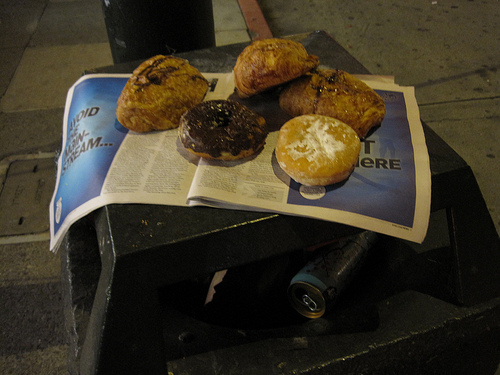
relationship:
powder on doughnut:
[291, 117, 347, 167] [272, 110, 363, 191]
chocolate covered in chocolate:
[180, 100, 268, 158] [180, 100, 268, 158]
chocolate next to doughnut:
[180, 100, 268, 158] [272, 110, 363, 191]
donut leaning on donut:
[229, 33, 321, 103] [272, 60, 388, 144]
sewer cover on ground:
[0, 158, 51, 237] [0, 2, 499, 374]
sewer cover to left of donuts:
[0, 158, 51, 237] [115, 37, 385, 187]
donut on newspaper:
[229, 33, 321, 103] [43, 68, 437, 258]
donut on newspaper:
[272, 60, 388, 144] [43, 68, 437, 258]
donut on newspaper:
[114, 49, 213, 136] [43, 68, 437, 258]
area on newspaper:
[104, 73, 289, 204] [43, 68, 437, 258]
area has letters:
[104, 73, 289, 204] [124, 143, 157, 155]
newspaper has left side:
[43, 68, 437, 258] [52, 77, 130, 235]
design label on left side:
[55, 197, 63, 224] [52, 77, 130, 235]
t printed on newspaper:
[360, 138, 376, 154] [43, 68, 437, 258]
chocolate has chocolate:
[180, 100, 268, 158] [180, 100, 268, 158]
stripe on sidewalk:
[236, 0, 274, 40] [0, 1, 251, 375]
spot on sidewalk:
[11, 103, 22, 112] [0, 1, 251, 375]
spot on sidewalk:
[47, 62, 56, 71] [0, 1, 251, 375]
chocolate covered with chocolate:
[180, 100, 268, 158] [180, 100, 268, 158]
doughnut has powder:
[272, 110, 363, 191] [291, 117, 347, 167]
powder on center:
[291, 117, 347, 167] [302, 130, 328, 154]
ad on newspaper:
[286, 92, 416, 228] [43, 68, 437, 258]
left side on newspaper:
[52, 77, 130, 235] [43, 68, 437, 258]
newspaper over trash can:
[43, 68, 437, 258] [61, 29, 498, 374]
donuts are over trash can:
[115, 37, 385, 187] [61, 29, 498, 374]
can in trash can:
[282, 222, 385, 319] [61, 29, 498, 374]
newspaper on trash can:
[43, 68, 437, 258] [61, 29, 498, 374]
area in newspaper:
[104, 73, 289, 204] [43, 68, 437, 258]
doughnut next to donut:
[272, 110, 363, 191] [272, 60, 388, 144]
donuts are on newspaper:
[115, 37, 385, 187] [43, 68, 437, 258]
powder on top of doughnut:
[291, 117, 347, 167] [272, 110, 363, 191]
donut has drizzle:
[272, 60, 388, 144] [311, 69, 344, 114]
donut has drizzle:
[114, 49, 213, 136] [137, 58, 178, 93]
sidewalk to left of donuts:
[0, 1, 251, 375] [115, 37, 385, 187]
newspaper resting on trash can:
[43, 68, 437, 258] [61, 29, 498, 374]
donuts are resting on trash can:
[115, 37, 385, 187] [61, 29, 498, 374]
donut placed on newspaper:
[229, 33, 321, 103] [43, 68, 437, 258]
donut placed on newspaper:
[114, 49, 213, 136] [43, 68, 437, 258]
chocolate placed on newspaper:
[180, 100, 268, 158] [43, 68, 437, 258]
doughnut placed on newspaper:
[272, 110, 363, 191] [43, 68, 437, 258]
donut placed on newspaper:
[272, 60, 388, 144] [43, 68, 437, 258]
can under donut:
[282, 222, 385, 319] [114, 49, 213, 136]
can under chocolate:
[282, 222, 385, 319] [180, 100, 268, 158]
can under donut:
[282, 222, 385, 319] [229, 33, 321, 103]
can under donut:
[282, 222, 385, 319] [272, 60, 388, 144]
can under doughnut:
[282, 222, 385, 319] [272, 110, 363, 191]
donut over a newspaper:
[114, 49, 213, 136] [43, 68, 437, 258]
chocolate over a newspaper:
[180, 100, 268, 158] [43, 68, 437, 258]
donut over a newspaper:
[229, 33, 321, 103] [43, 68, 437, 258]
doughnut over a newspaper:
[272, 110, 363, 191] [43, 68, 437, 258]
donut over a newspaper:
[272, 60, 388, 144] [43, 68, 437, 258]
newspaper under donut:
[43, 68, 437, 258] [114, 49, 213, 136]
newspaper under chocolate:
[43, 68, 437, 258] [180, 100, 268, 158]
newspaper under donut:
[43, 68, 437, 258] [229, 33, 321, 103]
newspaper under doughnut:
[43, 68, 437, 258] [272, 110, 363, 191]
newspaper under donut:
[43, 68, 437, 258] [272, 60, 388, 144]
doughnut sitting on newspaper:
[272, 110, 363, 191] [43, 68, 437, 258]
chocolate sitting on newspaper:
[180, 100, 268, 158] [43, 68, 437, 258]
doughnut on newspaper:
[272, 110, 363, 191] [43, 68, 437, 258]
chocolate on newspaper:
[180, 100, 268, 158] [43, 68, 437, 258]